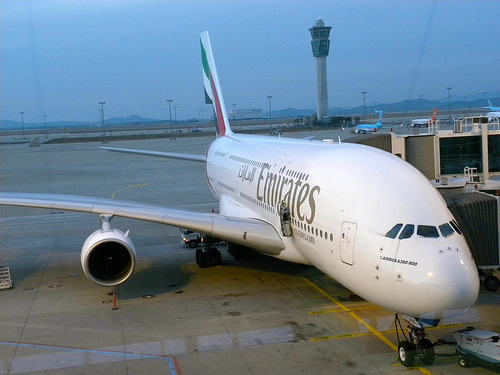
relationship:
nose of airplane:
[421, 252, 483, 312] [0, 31, 500, 367]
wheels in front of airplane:
[400, 339, 435, 366] [0, 31, 500, 367]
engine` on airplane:
[80, 229, 137, 289] [0, 31, 500, 367]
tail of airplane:
[200, 30, 233, 137] [0, 31, 500, 367]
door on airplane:
[340, 220, 357, 266] [0, 31, 500, 367]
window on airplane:
[329, 233, 335, 240] [0, 31, 500, 367]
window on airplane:
[319, 230, 324, 237] [0, 31, 500, 367]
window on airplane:
[308, 225, 311, 232] [0, 31, 500, 367]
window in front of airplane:
[416, 225, 440, 239] [0, 31, 500, 367]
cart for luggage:
[436, 134, 483, 184] [440, 140, 480, 172]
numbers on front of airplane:
[397, 259, 418, 267] [0, 31, 500, 367]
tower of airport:
[309, 19, 333, 125] [0, 107, 499, 374]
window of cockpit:
[416, 225, 440, 239] [377, 205, 466, 254]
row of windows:
[213, 151, 312, 182] [215, 152, 308, 182]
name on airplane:
[257, 164, 323, 225] [0, 31, 500, 367]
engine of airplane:
[80, 229, 137, 289] [0, 31, 500, 367]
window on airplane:
[416, 225, 440, 239] [0, 31, 500, 367]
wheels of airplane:
[400, 339, 435, 366] [0, 31, 500, 367]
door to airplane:
[340, 220, 357, 266] [0, 31, 500, 367]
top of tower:
[315, 18, 324, 26] [309, 19, 333, 125]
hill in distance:
[330, 98, 500, 116] [1, 0, 498, 129]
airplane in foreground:
[0, 31, 500, 367] [4, 120, 499, 374]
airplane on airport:
[0, 31, 500, 367] [0, 107, 499, 374]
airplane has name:
[0, 31, 500, 367] [257, 164, 323, 225]